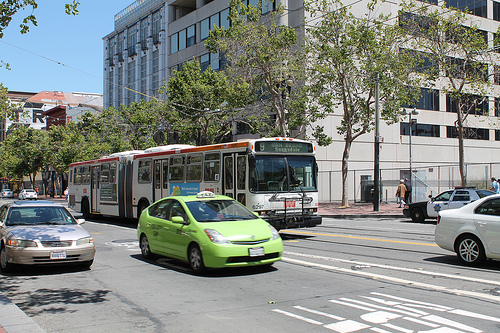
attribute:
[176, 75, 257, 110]
leaf — green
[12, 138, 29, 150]
leaf — green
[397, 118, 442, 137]
window — glass 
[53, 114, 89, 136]
leaf — green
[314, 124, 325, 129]
leaf — green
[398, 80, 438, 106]
window — glass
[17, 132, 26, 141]
leaf — green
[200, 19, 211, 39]
window — glass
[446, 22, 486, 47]
window — glass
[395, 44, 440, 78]
window — glass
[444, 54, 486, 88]
window — tinted, black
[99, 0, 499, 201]
building — multi-story, gray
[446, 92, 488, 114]
window — glass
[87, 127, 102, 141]
leaf — green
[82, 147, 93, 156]
leaf — green